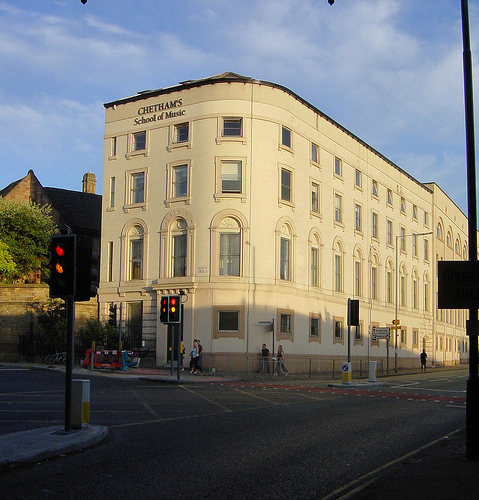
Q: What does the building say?
A: Chethams School of Music.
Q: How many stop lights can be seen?
A: 2,.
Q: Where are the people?
A: Next to the building.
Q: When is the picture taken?
A: Daytime.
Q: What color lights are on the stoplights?
A: Red and yellow.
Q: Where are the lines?
A: On the street.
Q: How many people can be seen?
A: 7.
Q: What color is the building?
A: Tan.